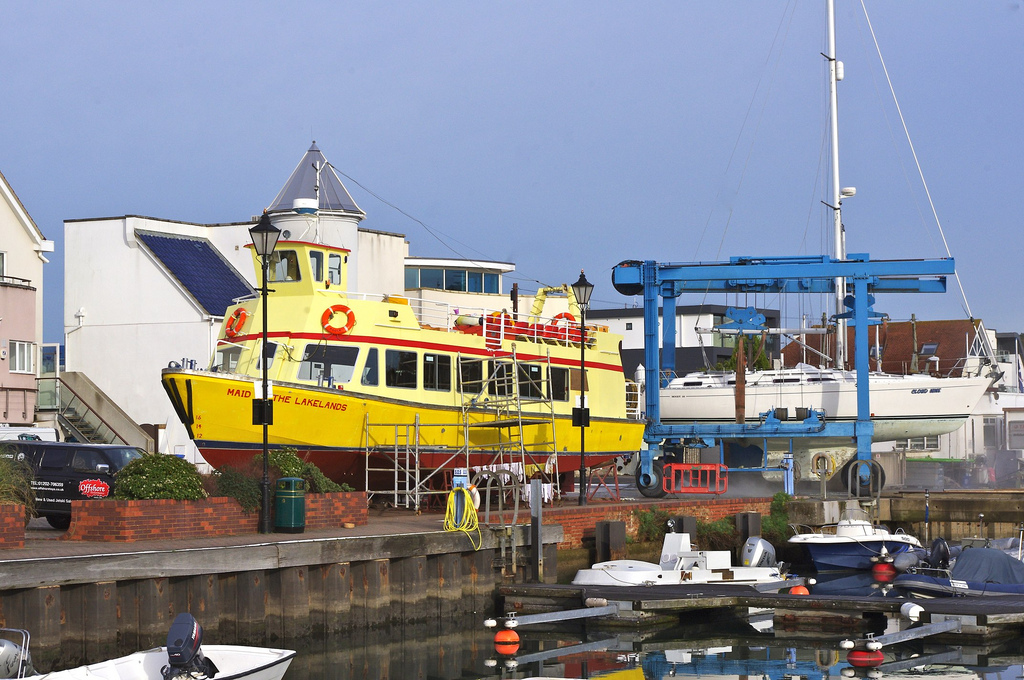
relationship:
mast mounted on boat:
[815, 1, 859, 367] [626, 3, 990, 449]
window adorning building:
[465, 269, 483, 291] [63, 215, 586, 479]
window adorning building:
[480, 268, 506, 297] [58, 134, 584, 491]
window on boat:
[511, 364, 546, 399] [153, 236, 657, 507]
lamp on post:
[247, 214, 284, 273] [260, 255, 280, 530]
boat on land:
[153, 236, 657, 507] [3, 459, 865, 676]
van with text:
[3, 437, 129, 528] [23, 476, 63, 503]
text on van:
[23, 476, 63, 503] [3, 437, 129, 528]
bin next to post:
[269, 474, 317, 546] [247, 214, 291, 543]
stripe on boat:
[231, 318, 630, 379] [153, 236, 657, 507]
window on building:
[36, 342, 75, 379] [0, 186, 85, 454]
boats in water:
[534, 506, 986, 669] [289, 593, 469, 674]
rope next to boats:
[440, 478, 488, 533] [514, 510, 990, 657]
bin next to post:
[274, 477, 306, 533] [247, 205, 283, 533]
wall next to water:
[101, 530, 512, 624] [350, 627, 495, 677]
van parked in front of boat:
[22, 431, 152, 525] [153, 236, 657, 507]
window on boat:
[292, 338, 360, 386] [153, 236, 657, 507]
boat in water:
[875, 532, 992, 626] [402, 592, 759, 675]